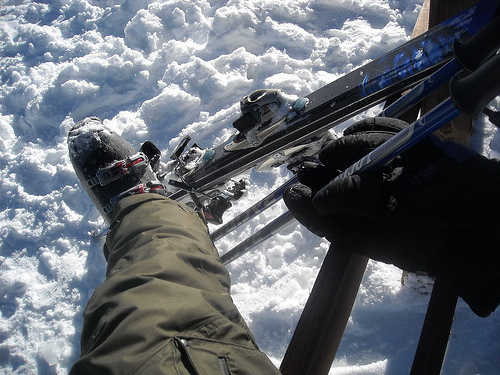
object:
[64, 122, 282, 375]
leg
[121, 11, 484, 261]
skis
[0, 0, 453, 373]
snow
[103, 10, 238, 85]
white snow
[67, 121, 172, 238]
boot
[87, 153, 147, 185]
latch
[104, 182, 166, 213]
latch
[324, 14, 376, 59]
white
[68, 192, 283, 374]
pants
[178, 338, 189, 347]
button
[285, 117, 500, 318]
black gloves